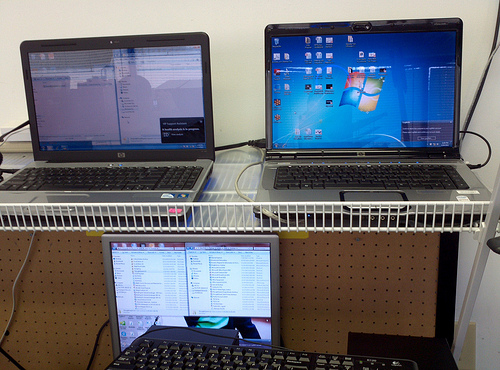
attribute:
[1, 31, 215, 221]
laptop — hp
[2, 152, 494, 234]
shelf — white, wire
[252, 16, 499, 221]
laptop — hp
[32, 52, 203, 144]
background — grey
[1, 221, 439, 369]
pegboard — brown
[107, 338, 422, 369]
keyboard — black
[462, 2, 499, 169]
cord — black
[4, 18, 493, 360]
computers — grey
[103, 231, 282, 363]
monitor — on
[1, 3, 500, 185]
wall — white, wood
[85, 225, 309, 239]
tape — yellow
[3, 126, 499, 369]
display — white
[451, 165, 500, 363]
pole — light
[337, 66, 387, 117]
logo — windows